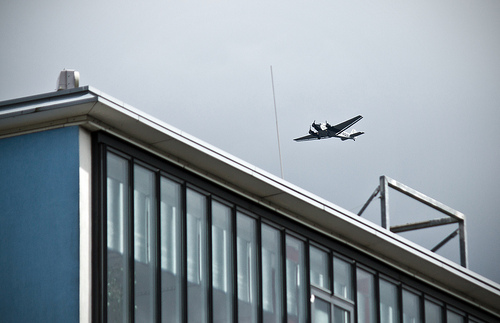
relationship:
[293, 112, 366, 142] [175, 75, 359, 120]
plane in air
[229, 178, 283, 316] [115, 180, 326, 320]
window on side of building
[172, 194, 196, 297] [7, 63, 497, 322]
window on building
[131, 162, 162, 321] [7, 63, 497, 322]
window on side of building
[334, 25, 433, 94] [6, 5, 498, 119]
clouds in sky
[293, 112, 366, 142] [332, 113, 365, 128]
plane has wing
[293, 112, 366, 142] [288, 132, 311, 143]
plane has wing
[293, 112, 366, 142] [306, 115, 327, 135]
plane has front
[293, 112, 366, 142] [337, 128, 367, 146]
plane has back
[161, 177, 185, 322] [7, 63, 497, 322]
window on building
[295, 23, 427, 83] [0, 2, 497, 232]
clouds in sky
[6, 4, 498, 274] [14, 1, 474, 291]
cloud in sky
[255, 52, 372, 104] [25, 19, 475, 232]
clouds in sky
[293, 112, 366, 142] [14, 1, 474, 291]
plane in sky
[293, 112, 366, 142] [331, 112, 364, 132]
plane has wing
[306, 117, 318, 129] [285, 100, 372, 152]
propeller on plane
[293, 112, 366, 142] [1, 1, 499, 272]
plane in sky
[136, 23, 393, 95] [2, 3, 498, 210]
clouds in sky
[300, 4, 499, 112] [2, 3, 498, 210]
clouds in sky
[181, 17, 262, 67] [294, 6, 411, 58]
clouds in sky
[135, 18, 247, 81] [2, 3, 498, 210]
clouds in sky